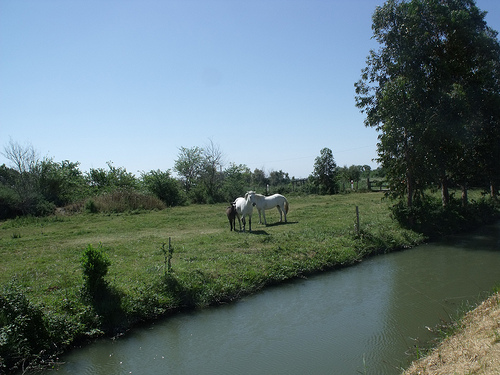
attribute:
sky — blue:
[0, 5, 499, 202]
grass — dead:
[407, 287, 499, 373]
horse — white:
[232, 185, 262, 237]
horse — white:
[247, 189, 287, 225]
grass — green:
[0, 187, 492, 355]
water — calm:
[17, 225, 497, 373]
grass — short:
[124, 206, 276, 268]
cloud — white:
[1, 135, 223, 180]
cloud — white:
[170, 147, 387, 168]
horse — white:
[236, 190, 289, 224]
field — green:
[17, 209, 224, 286]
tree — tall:
[369, 3, 435, 218]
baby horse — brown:
[219, 206, 239, 228]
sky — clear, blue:
[3, 5, 406, 182]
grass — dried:
[401, 290, 498, 372]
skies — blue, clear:
[94, 26, 311, 161]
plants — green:
[156, 237, 183, 281]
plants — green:
[76, 239, 123, 313]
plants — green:
[0, 290, 78, 361]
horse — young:
[220, 180, 264, 229]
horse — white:
[239, 187, 292, 229]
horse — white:
[228, 187, 263, 234]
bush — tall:
[57, 240, 134, 324]